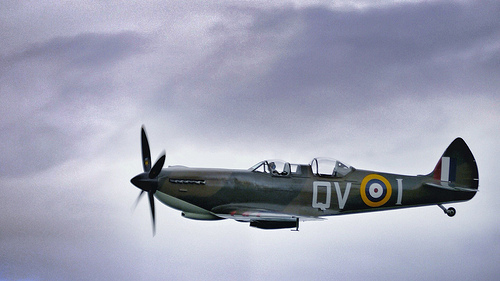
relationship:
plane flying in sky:
[130, 125, 479, 236] [1, 0, 498, 280]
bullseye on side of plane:
[359, 174, 392, 208] [130, 125, 479, 236]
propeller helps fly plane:
[131, 125, 166, 238] [130, 125, 479, 236]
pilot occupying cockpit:
[267, 163, 279, 177] [250, 159, 300, 178]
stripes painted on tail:
[433, 157, 458, 182] [431, 136, 479, 204]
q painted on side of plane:
[312, 181, 331, 213] [130, 125, 479, 236]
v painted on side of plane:
[334, 181, 352, 211] [130, 125, 479, 236]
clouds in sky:
[1, 0, 499, 280] [1, 0, 498, 280]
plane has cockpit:
[130, 125, 479, 236] [250, 159, 300, 178]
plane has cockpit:
[130, 125, 479, 236] [310, 158, 354, 177]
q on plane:
[312, 181, 331, 213] [130, 125, 479, 236]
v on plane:
[334, 181, 352, 211] [130, 125, 479, 236]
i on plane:
[394, 177, 404, 207] [130, 125, 479, 236]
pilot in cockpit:
[267, 163, 279, 177] [250, 159, 300, 178]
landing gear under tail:
[438, 204, 456, 218] [431, 136, 479, 204]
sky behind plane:
[1, 0, 498, 280] [130, 125, 479, 236]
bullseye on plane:
[359, 174, 392, 208] [130, 125, 479, 236]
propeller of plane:
[131, 125, 166, 238] [130, 125, 479, 236]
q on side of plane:
[312, 181, 331, 213] [130, 125, 479, 236]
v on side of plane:
[334, 181, 352, 211] [130, 125, 479, 236]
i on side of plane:
[394, 177, 404, 207] [130, 125, 479, 236]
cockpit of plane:
[310, 158, 354, 177] [130, 125, 479, 236]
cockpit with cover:
[310, 158, 354, 177] [312, 159, 340, 176]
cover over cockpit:
[312, 159, 340, 176] [310, 158, 354, 177]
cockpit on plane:
[310, 158, 354, 177] [130, 125, 479, 236]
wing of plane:
[210, 203, 329, 230] [130, 125, 479, 236]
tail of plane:
[431, 136, 479, 204] [130, 125, 479, 236]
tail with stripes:
[431, 136, 479, 204] [433, 157, 458, 182]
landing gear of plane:
[438, 204, 456, 218] [130, 125, 479, 236]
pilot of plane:
[267, 163, 279, 177] [130, 125, 479, 236]